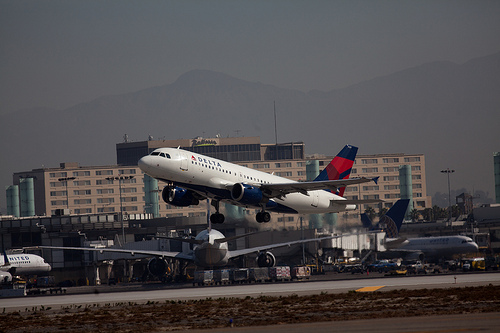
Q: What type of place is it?
A: It is an airport.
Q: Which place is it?
A: It is an airport.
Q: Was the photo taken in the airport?
A: Yes, it was taken in the airport.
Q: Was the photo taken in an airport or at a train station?
A: It was taken at an airport.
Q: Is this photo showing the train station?
A: No, the picture is showing the airport.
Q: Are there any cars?
A: No, there are no cars.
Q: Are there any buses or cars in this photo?
A: No, there are no cars or buses.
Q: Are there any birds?
A: No, there are no birds.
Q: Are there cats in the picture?
A: No, there are no cats.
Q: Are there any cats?
A: No, there are no cats.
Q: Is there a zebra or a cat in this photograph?
A: No, there are no cats or zebras.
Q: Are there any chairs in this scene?
A: No, there are no chairs.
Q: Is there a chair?
A: No, there are no chairs.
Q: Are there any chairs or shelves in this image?
A: No, there are no chairs or shelves.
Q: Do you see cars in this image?
A: No, there are no cars.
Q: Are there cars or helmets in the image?
A: No, there are no cars or helmets.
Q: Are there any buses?
A: No, there are no buses.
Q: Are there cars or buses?
A: No, there are no buses or cars.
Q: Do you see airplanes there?
A: Yes, there is an airplane.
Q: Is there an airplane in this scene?
A: Yes, there is an airplane.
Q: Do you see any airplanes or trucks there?
A: Yes, there is an airplane.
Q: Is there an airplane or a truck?
A: Yes, there is an airplane.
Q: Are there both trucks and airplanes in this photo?
A: No, there is an airplane but no trucks.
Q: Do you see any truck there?
A: No, there are no trucks.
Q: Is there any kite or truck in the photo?
A: No, there are no trucks or kites.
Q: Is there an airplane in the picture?
A: Yes, there is an airplane.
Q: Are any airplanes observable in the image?
A: Yes, there is an airplane.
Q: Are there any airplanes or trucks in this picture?
A: Yes, there is an airplane.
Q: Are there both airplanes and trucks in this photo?
A: No, there is an airplane but no trucks.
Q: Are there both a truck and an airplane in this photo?
A: No, there is an airplane but no trucks.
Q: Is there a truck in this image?
A: No, there are no trucks.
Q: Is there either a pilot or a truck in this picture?
A: No, there are no trucks or pilots.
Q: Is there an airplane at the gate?
A: Yes, there is an airplane at the gate.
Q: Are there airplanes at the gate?
A: Yes, there is an airplane at the gate.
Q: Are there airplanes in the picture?
A: Yes, there is an airplane.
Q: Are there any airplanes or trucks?
A: Yes, there is an airplane.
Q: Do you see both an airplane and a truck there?
A: No, there is an airplane but no trucks.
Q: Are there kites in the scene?
A: No, there are no kites.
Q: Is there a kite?
A: No, there are no kites.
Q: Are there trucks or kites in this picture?
A: No, there are no kites or trucks.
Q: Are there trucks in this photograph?
A: No, there are no trucks.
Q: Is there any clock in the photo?
A: No, there are no clocks.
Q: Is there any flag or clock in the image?
A: No, there are no clocks or flags.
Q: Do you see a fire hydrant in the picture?
A: No, there are no fire hydrants.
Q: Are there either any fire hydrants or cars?
A: No, there are no fire hydrants or cars.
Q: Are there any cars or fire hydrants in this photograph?
A: No, there are no fire hydrants or cars.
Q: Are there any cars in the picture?
A: No, there are no cars.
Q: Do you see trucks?
A: No, there are no trucks.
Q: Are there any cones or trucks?
A: No, there are no trucks or cones.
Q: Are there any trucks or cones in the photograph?
A: No, there are no trucks or cones.